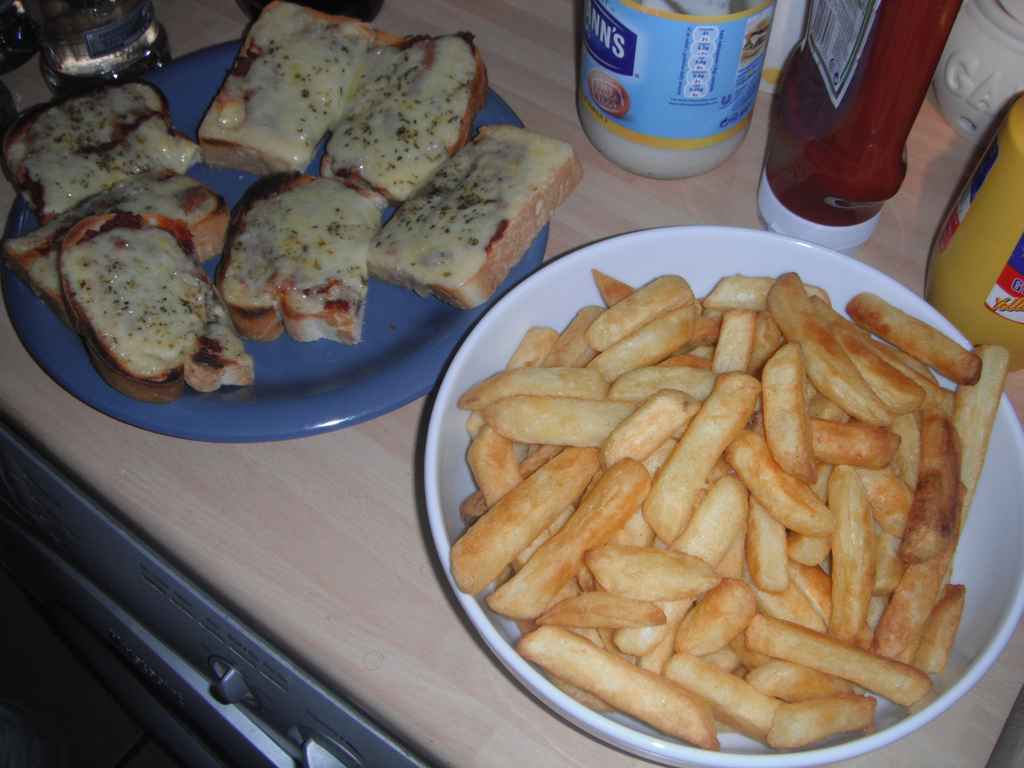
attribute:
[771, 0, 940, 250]
ketchup — bottled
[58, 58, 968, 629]
food — spiced, served, melted, small, fried, brown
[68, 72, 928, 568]
plate — blue, white, full, round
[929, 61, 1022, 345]
mustard — yellow, bottled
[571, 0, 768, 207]
mayo — jarred, labeled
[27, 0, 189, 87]
glass — full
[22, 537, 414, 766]
oven — silver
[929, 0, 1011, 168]
jar — white